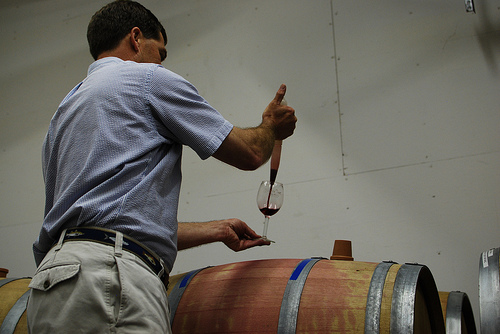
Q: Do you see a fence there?
A: No, there are no fences.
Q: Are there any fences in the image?
A: No, there are no fences.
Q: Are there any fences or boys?
A: No, there are no fences or boys.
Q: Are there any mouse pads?
A: No, there are no mouse pads.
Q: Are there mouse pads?
A: No, there are no mouse pads.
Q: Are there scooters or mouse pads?
A: No, there are no mouse pads or scooters.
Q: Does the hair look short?
A: Yes, the hair is short.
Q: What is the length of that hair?
A: The hair is short.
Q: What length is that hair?
A: The hair is short.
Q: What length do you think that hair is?
A: The hair is short.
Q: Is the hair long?
A: No, the hair is short.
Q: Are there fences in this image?
A: No, there are no fences.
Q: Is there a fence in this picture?
A: No, there are no fences.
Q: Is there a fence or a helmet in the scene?
A: No, there are no fences or helmets.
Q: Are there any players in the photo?
A: No, there are no players.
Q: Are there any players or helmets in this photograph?
A: No, there are no players or helmets.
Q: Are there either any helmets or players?
A: No, there are no players or helmets.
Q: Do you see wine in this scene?
A: Yes, there is wine.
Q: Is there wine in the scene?
A: Yes, there is wine.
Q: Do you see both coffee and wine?
A: No, there is wine but no coffee.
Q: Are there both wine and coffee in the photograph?
A: No, there is wine but no coffee.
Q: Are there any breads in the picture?
A: No, there are no breads.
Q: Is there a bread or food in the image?
A: No, there are no breads or food.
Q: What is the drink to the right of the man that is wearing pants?
A: The drink is wine.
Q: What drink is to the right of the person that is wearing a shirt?
A: The drink is wine.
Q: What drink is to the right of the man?
A: The drink is wine.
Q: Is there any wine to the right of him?
A: Yes, there is wine to the right of the man.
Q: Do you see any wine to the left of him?
A: No, the wine is to the right of the man.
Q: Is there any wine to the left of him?
A: No, the wine is to the right of the man.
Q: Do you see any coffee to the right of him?
A: No, there is wine to the right of the man.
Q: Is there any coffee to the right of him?
A: No, there is wine to the right of the man.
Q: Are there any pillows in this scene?
A: No, there are no pillows.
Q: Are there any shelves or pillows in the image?
A: No, there are no pillows or shelves.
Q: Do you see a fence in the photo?
A: No, there are no fences.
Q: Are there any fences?
A: No, there are no fences.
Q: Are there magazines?
A: No, there are no magazines.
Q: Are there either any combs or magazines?
A: No, there are no magazines or combs.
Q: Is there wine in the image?
A: Yes, there is wine.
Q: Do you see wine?
A: Yes, there is wine.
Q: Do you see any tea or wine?
A: Yes, there is wine.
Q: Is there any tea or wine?
A: Yes, there is wine.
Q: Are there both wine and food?
A: No, there is wine but no food.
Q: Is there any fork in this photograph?
A: No, there are no forks.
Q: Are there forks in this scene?
A: No, there are no forks.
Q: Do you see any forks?
A: No, there are no forks.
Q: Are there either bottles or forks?
A: No, there are no forks or bottles.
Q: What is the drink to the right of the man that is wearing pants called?
A: The drink is wine.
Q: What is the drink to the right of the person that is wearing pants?
A: The drink is wine.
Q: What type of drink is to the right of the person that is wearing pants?
A: The drink is wine.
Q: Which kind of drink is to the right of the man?
A: The drink is wine.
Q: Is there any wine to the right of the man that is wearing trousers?
A: Yes, there is wine to the right of the man.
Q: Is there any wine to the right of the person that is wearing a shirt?
A: Yes, there is wine to the right of the man.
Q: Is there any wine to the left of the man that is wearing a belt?
A: No, the wine is to the right of the man.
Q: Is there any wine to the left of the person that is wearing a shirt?
A: No, the wine is to the right of the man.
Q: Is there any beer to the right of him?
A: No, there is wine to the right of the man.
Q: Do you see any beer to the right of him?
A: No, there is wine to the right of the man.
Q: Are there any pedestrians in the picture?
A: No, there are no pedestrians.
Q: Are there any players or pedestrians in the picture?
A: No, there are no pedestrians or players.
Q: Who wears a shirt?
A: The man wears a shirt.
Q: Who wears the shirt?
A: The man wears a shirt.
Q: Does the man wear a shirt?
A: Yes, the man wears a shirt.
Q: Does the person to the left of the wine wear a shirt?
A: Yes, the man wears a shirt.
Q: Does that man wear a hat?
A: No, the man wears a shirt.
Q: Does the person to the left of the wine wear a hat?
A: No, the man wears a shirt.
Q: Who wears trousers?
A: The man wears trousers.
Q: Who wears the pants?
A: The man wears trousers.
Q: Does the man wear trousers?
A: Yes, the man wears trousers.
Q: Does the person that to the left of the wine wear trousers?
A: Yes, the man wears trousers.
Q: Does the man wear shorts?
A: No, the man wears trousers.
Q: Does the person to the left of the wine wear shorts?
A: No, the man wears trousers.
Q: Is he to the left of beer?
A: No, the man is to the left of the wine.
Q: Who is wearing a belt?
A: The man is wearing a belt.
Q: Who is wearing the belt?
A: The man is wearing a belt.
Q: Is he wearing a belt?
A: Yes, the man is wearing a belt.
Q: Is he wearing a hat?
A: No, the man is wearing a belt.